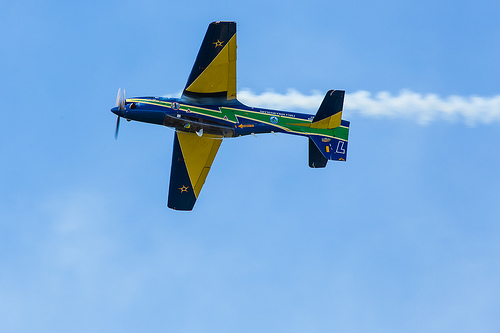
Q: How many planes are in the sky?
A: One.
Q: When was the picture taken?
A: Daytime.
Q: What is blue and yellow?
A: Plane.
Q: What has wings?
A: The plane.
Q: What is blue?
A: Sky.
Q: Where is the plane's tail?
A: On the back.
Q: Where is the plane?
A: In the air.